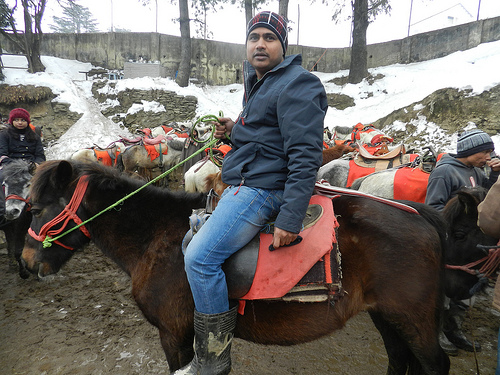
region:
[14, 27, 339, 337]
a man sitting on a horse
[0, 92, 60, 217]
a child sitting on a horse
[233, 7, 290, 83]
a man wearing a cap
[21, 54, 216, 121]
snow covering the ground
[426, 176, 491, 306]
a black horse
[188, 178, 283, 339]
a man wearing jeans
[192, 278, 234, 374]
a man wearing rubber boots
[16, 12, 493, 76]
a long concrete wall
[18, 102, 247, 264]
a green rope tied to a horse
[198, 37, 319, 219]
a man wearing a blue coat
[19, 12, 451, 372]
a man on a small donkey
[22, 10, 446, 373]
a man riding a small mule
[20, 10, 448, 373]
a man riding a small horse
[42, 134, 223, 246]
a green rope used as reins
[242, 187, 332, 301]
a pink saddle blanket on the pony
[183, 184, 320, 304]
a riding saddle on the pony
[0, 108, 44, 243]
a small person riding a small animal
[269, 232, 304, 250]
a brown object in the man's hand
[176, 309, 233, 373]
a grubby looking black boot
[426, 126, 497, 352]
a young man wearing a hoodie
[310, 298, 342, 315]
part of a stomach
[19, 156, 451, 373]
A small brown horse.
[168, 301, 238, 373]
A dirty black boot a man on a horse is wearing.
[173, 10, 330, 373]
A dark skinned man on a horse wearing a blue coat.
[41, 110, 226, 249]
A green rope a man is holding going to a horses face.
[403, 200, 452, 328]
Thin black tail of a solid brown horse.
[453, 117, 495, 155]
Blue and white toboggin on a man's head to the right of a brown horse.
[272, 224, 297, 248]
A man's left hand holding black sunglasses.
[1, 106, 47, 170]
A person in a red cap on a horse to the left.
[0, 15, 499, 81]
A long concrete wall up on the hill going from left to right.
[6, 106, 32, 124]
A red hat on a persons head.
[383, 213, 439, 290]
part of a horse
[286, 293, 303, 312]
part of a horse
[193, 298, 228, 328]
edge of a boot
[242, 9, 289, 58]
tight plaid winter hat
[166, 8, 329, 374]
man sitting on a horse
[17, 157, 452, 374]
dark brown and black pony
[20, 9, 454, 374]
dark pony carrying a man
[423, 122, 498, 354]
man wearing a winter hat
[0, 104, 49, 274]
woman wearing a burgundy hat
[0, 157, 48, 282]
white and black pony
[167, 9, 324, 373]
man wearing rubber boots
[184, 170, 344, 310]
saddle on top of a horse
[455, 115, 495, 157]
dark and light grey hat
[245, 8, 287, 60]
plaid winter hat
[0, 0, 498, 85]
cement wall under fence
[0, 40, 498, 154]
snow on ground surface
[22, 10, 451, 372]
man sitting on horse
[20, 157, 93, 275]
red bridle on horse head